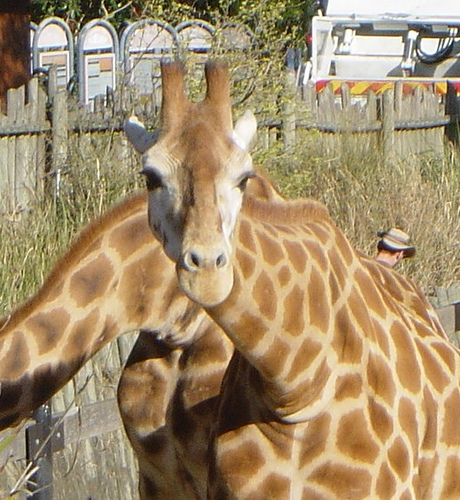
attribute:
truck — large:
[295, 1, 459, 105]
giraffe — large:
[0, 59, 458, 498]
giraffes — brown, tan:
[49, 127, 394, 488]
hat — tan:
[357, 219, 439, 271]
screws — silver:
[35, 429, 58, 448]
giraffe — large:
[109, 47, 457, 498]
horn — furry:
[159, 60, 188, 121]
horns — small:
[152, 43, 230, 104]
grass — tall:
[31, 122, 454, 268]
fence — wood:
[4, 77, 436, 192]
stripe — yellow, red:
[308, 74, 446, 99]